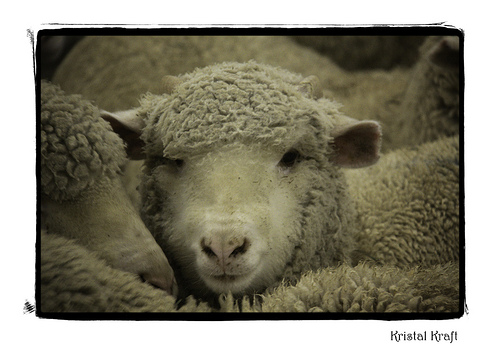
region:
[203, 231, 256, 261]
Pink nose on a sheep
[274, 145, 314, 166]
Eye in a sheep's head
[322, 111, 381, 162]
Ear on a sheep's head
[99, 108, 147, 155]
Ear on a sheep's head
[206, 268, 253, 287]
Sheep's mouth under its nose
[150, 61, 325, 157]
White wooly sheep's head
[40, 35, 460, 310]
Herd of sheep huddled together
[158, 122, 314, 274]
The face of the sheep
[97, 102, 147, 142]
The left ear of the sheep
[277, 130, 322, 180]
The right eye of the sheep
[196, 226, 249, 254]
The nose of the sheep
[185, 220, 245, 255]
The pink nose of the sheep.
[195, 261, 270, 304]
The mouth of the sheep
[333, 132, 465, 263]
The wool of the sheep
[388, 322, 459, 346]
The person who took the picture.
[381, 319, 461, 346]
words on the corner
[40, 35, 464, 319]
a group of sheep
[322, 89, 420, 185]
a sheep's ear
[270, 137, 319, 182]
a sheep's eye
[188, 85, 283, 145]
a sheep's forehead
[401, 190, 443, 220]
a patch of wool on a sheep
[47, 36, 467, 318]
some animals in a herd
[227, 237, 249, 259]
THE NOSTRIL OF A SHEEP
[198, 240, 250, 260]
the nostrils of a sheep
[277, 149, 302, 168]
left eye of a sheep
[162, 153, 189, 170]
right eye of a sheep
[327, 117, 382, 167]
the left ear of a sheep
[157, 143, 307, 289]
the smooth part of a sheep's face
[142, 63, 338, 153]
wool on a sheep's head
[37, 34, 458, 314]
crowded group of sheep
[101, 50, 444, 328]
this is a sheep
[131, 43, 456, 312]
the sheep is tan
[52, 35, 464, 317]
a group of sheeps together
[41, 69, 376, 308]
two sheep faces together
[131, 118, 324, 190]
eyes on the sheep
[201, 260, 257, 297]
mouth on the sheep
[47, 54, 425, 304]
this is a sheep